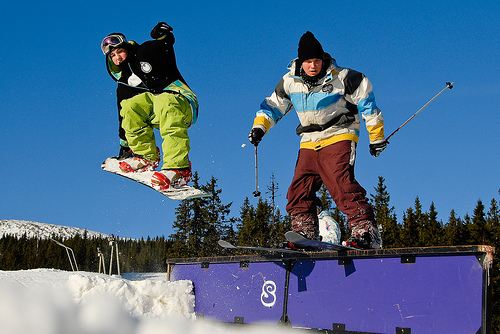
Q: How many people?
A: 2.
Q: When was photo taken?
A: Daytime.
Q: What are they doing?
A: Skiing.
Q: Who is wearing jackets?
A: Skiers.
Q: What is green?
A: Snowpants.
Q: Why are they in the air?
A: Jumping.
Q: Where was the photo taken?
A: Ski resort.